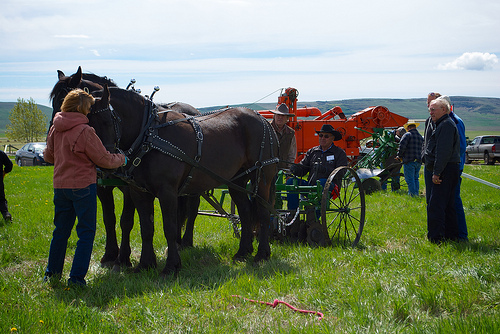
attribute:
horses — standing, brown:
[98, 72, 300, 278]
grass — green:
[302, 254, 422, 309]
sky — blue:
[123, 14, 230, 54]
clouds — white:
[172, 15, 273, 62]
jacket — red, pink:
[36, 104, 125, 192]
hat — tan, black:
[306, 115, 353, 147]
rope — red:
[224, 273, 341, 329]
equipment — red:
[284, 90, 406, 179]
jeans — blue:
[40, 182, 112, 282]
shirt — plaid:
[397, 134, 422, 162]